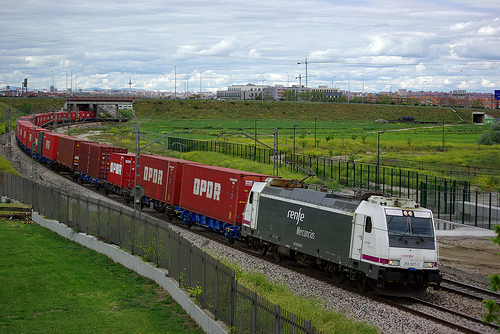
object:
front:
[374, 203, 439, 274]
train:
[15, 110, 442, 294]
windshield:
[387, 215, 436, 250]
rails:
[167, 223, 500, 333]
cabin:
[349, 197, 438, 271]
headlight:
[389, 260, 399, 266]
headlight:
[423, 262, 434, 267]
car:
[37, 132, 47, 156]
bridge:
[61, 97, 140, 120]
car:
[179, 164, 281, 224]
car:
[108, 153, 139, 187]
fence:
[1, 163, 323, 334]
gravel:
[366, 305, 394, 322]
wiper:
[398, 228, 408, 241]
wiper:
[414, 231, 425, 242]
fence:
[167, 135, 500, 236]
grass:
[132, 112, 500, 189]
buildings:
[216, 90, 263, 98]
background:
[0, 68, 499, 111]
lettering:
[287, 207, 305, 225]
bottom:
[177, 207, 242, 239]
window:
[365, 217, 372, 233]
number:
[403, 262, 419, 266]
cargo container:
[56, 137, 98, 169]